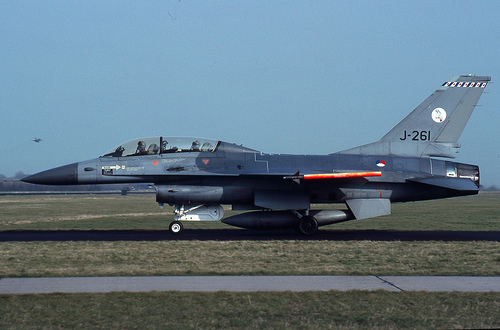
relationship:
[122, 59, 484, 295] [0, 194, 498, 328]
jet on ground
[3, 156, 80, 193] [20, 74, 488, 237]
nose of jet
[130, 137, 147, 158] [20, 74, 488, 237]
person inside jet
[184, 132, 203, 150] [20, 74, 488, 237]
person inside jet